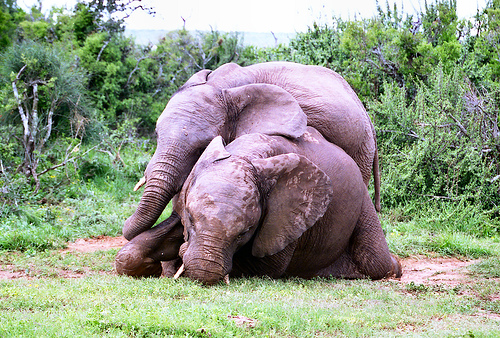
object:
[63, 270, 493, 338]
grass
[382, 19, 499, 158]
trees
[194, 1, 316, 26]
sky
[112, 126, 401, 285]
elephant